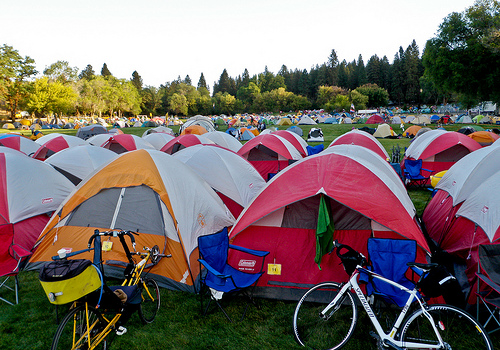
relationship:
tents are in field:
[1, 132, 499, 295] [7, 103, 499, 346]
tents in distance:
[7, 110, 499, 126] [3, 4, 499, 124]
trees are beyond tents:
[1, 45, 496, 106] [1, 132, 499, 295]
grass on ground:
[5, 277, 494, 348] [7, 103, 499, 346]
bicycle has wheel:
[286, 240, 493, 348] [290, 276, 362, 348]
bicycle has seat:
[286, 240, 493, 348] [404, 258, 437, 285]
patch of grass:
[164, 300, 241, 348] [5, 277, 494, 348]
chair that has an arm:
[401, 154, 434, 192] [420, 165, 434, 178]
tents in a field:
[1, 132, 499, 295] [7, 103, 499, 346]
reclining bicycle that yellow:
[49, 226, 175, 350] [43, 242, 167, 339]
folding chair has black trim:
[1, 223, 21, 309] [11, 240, 35, 262]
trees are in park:
[1, 45, 496, 106] [2, 42, 495, 345]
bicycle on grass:
[286, 240, 493, 348] [5, 277, 494, 348]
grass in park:
[5, 277, 494, 348] [2, 42, 495, 345]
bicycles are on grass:
[45, 227, 494, 345] [5, 277, 494, 348]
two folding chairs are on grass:
[190, 225, 435, 325] [5, 277, 494, 348]